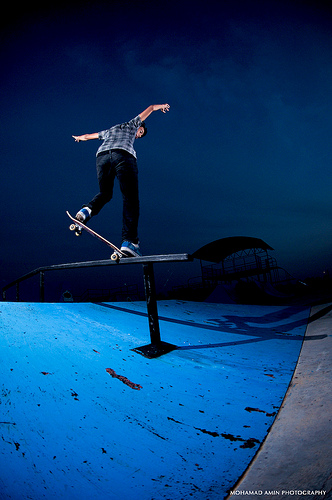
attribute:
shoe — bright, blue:
[117, 237, 144, 259]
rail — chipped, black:
[0, 242, 190, 365]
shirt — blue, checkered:
[99, 117, 138, 153]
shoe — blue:
[120, 238, 147, 256]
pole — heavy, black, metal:
[141, 267, 159, 346]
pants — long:
[79, 147, 140, 250]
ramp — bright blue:
[1, 296, 305, 496]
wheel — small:
[61, 219, 83, 237]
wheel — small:
[108, 247, 121, 265]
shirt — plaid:
[95, 115, 143, 160]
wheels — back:
[69, 223, 85, 237]